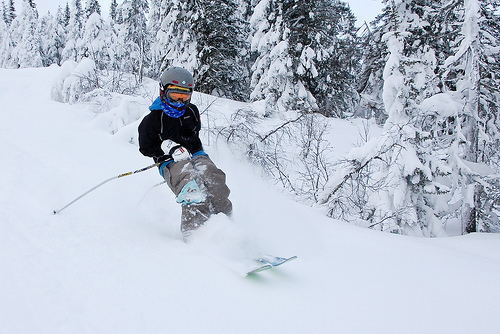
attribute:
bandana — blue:
[148, 92, 185, 117]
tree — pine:
[168, 0, 248, 100]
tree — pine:
[245, 2, 352, 105]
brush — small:
[225, 103, 344, 213]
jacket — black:
[127, 107, 218, 156]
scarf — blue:
[141, 99, 235, 136]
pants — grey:
[148, 150, 274, 232]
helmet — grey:
[157, 67, 194, 102]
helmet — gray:
[154, 64, 195, 107]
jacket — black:
[132, 106, 212, 158]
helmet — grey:
[158, 66, 193, 108]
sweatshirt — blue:
[135, 95, 202, 161]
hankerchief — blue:
[147, 92, 193, 119]